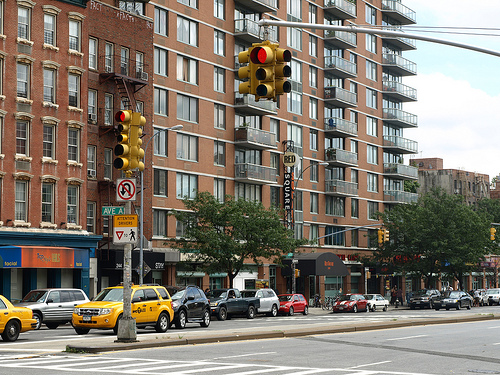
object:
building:
[0, 0, 418, 310]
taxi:
[74, 281, 175, 333]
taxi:
[0, 295, 38, 342]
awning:
[283, 251, 347, 276]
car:
[332, 292, 371, 313]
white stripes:
[340, 300, 347, 306]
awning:
[0, 245, 91, 271]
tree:
[168, 189, 319, 291]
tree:
[362, 180, 500, 289]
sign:
[116, 178, 138, 202]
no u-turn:
[120, 183, 133, 196]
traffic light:
[236, 39, 294, 100]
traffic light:
[112, 107, 146, 176]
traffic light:
[376, 227, 391, 245]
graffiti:
[88, 0, 154, 32]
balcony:
[324, 179, 359, 200]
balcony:
[326, 147, 359, 168]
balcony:
[324, 115, 358, 136]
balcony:
[323, 84, 357, 109]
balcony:
[321, 54, 360, 81]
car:
[166, 284, 212, 325]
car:
[432, 289, 476, 311]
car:
[362, 293, 391, 311]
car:
[277, 292, 311, 315]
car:
[241, 288, 281, 315]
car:
[204, 288, 261, 317]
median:
[66, 312, 499, 355]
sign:
[113, 215, 140, 245]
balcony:
[100, 54, 150, 90]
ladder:
[114, 76, 138, 112]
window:
[174, 130, 200, 163]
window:
[177, 91, 201, 124]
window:
[177, 53, 198, 86]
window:
[177, 171, 199, 202]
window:
[177, 13, 201, 49]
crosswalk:
[1, 346, 434, 374]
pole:
[118, 174, 138, 341]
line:
[201, 288, 310, 315]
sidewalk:
[307, 305, 332, 315]